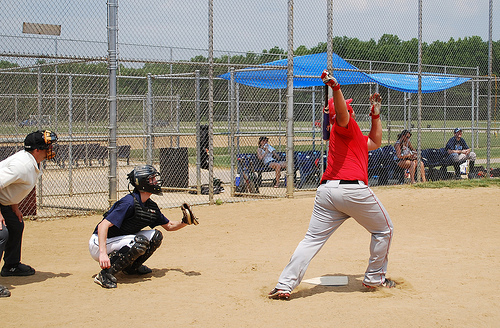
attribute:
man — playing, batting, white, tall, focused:
[269, 67, 408, 306]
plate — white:
[297, 268, 354, 294]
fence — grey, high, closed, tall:
[3, 0, 498, 179]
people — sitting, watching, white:
[242, 118, 479, 194]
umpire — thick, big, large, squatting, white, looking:
[1, 124, 66, 305]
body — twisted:
[268, 65, 396, 297]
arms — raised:
[317, 67, 383, 147]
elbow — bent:
[162, 219, 178, 234]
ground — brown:
[1, 184, 499, 324]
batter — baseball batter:
[269, 67, 396, 301]